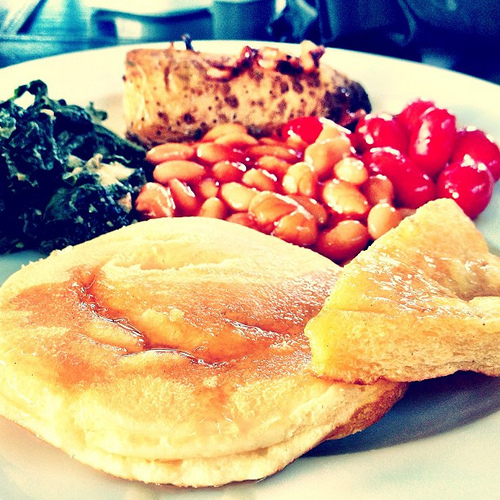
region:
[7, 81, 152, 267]
Cooked spinach on plate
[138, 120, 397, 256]
Baked beans on plate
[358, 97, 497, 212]
Red beans on plate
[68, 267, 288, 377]
Moisture marks from coooking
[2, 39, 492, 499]
Round white plate with food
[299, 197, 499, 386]
Piece of bread on plate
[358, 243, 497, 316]
Melted butter on bread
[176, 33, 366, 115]
Cooking burn marks on food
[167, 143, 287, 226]
Molasses sauce of baked beans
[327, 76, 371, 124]
Burnt end of food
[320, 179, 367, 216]
brown bean in sauce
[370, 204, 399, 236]
brown bean in sauce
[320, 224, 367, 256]
brown bean in sauce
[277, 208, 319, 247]
brown bean in sauce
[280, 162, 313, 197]
brown bean in sauce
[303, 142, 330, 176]
brown bean in sauce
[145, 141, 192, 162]
brown bean in sauce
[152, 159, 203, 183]
brown bean in sauce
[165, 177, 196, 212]
brown bean in sauce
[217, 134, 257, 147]
brown bean in sauce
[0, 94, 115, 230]
spinich on a plate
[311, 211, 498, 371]
corn bread on plate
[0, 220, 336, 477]
a biscuit on a plate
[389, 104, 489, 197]
red beans on plate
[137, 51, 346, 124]
baked chicken on the plate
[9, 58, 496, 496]
white plate holding food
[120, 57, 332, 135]
meat on the plate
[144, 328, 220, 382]
syrup on the biscuit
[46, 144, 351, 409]
this is a healthy meal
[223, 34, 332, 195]
this is some chicken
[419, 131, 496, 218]
the tomatoes are red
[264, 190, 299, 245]
these are pinto beans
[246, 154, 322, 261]
the beans are brown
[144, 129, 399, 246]
baked beans on the plate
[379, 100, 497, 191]
tomatoes on the plate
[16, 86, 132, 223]
spinach on the plate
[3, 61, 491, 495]
a large white plate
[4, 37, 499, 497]
a plate full of food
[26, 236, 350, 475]
bread on the plate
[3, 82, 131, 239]
vegetables on the plate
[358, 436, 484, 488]
the white plate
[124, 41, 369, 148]
browned piece of barbequed chicken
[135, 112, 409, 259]
pile of tan beans in sauce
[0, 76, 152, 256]
green spinach on the side of the plate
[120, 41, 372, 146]
small piece of barbequed chicken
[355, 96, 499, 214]
shiny red vegetable on a plate